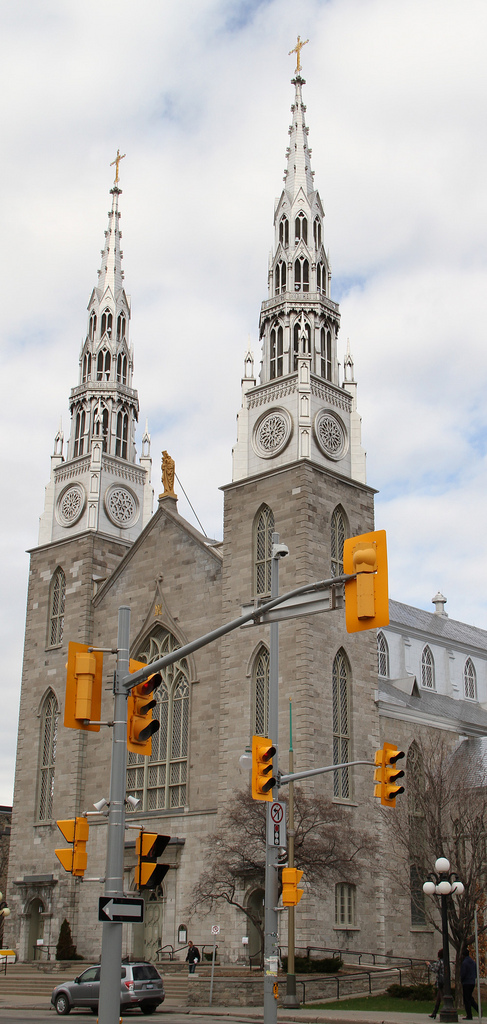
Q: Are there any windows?
A: Yes, there is a window.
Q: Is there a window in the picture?
A: Yes, there is a window.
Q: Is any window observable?
A: Yes, there is a window.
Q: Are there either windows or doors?
A: Yes, there is a window.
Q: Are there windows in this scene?
A: Yes, there is a window.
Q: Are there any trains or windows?
A: Yes, there is a window.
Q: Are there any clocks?
A: No, there are no clocks.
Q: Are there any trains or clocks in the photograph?
A: No, there are no clocks or trains.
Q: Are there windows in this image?
A: Yes, there is a window.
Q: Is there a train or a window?
A: Yes, there is a window.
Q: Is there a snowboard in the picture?
A: No, there are no snowboards.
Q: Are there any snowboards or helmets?
A: No, there are no snowboards or helmets.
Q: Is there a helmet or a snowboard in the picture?
A: No, there are no snowboards or helmets.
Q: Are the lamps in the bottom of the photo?
A: Yes, the lamps are in the bottom of the image.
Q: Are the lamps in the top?
A: No, the lamps are in the bottom of the image.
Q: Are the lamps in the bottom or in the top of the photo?
A: The lamps are in the bottom of the image.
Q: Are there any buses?
A: No, there are no buses.